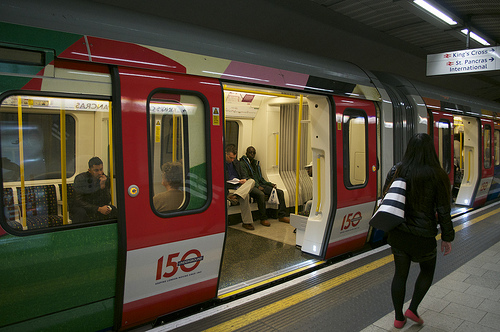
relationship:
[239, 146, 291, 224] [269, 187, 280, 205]
man holding bag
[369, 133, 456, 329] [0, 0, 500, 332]
female next to subway car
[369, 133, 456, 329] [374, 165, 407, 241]
female carrying bag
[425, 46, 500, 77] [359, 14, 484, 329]
sign in station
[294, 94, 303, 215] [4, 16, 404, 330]
bars in subway car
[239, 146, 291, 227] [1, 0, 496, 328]
man sitting in subway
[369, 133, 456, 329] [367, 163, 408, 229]
female carrying bag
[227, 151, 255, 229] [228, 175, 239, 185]
man reading newspaper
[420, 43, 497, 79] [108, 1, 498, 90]
sign hanging from ceiling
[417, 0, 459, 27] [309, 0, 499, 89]
light on ceiling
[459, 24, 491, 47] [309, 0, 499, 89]
light on ceiling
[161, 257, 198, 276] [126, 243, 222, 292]
numbers on background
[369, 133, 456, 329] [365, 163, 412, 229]
female has bag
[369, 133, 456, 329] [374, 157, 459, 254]
female has coat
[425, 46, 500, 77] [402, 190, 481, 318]
sign hanging over platform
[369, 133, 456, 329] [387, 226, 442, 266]
female has skirt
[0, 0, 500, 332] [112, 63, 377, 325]
subway car has doors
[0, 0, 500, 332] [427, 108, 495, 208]
subway car has door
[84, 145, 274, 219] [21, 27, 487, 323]
people sitting in train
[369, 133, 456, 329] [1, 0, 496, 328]
female in subway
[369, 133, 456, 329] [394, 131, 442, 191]
female has hair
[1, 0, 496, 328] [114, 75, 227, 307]
subway has door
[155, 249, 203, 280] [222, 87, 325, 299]
numbers on subway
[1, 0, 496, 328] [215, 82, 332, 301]
subway has open door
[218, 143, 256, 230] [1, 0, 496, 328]
man in subway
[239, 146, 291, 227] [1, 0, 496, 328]
man in subway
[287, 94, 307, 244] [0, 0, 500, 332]
bars inside subway car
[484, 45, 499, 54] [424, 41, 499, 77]
arrows are in sign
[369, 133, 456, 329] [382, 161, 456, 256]
female wearing coat